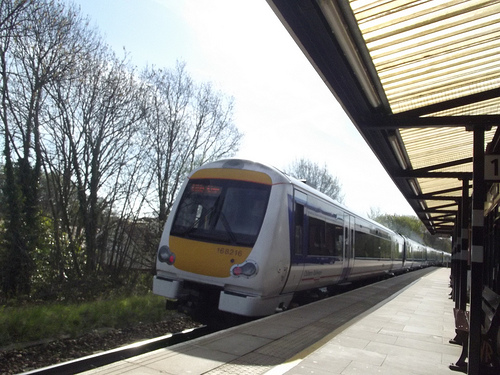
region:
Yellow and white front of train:
[147, 156, 287, 318]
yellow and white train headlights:
[227, 253, 267, 283]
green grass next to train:
[1, 285, 176, 338]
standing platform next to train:
[75, 262, 470, 374]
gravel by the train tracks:
[3, 307, 193, 374]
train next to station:
[143, 150, 468, 318]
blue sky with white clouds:
[1, 1, 425, 223]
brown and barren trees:
[0, 0, 244, 311]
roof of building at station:
[264, 0, 499, 239]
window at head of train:
[166, 175, 275, 247]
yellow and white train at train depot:
[164, 153, 426, 295]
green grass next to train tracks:
[10, 296, 152, 330]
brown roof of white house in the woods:
[101, 217, 151, 272]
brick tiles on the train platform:
[377, 315, 408, 374]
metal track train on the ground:
[65, 346, 152, 352]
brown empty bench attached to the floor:
[451, 269, 498, 373]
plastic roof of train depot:
[395, 70, 474, 199]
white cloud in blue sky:
[183, 12, 218, 45]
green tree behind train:
[380, 204, 423, 230]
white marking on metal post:
[471, 189, 487, 271]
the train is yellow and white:
[122, 145, 457, 321]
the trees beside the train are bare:
[2, 0, 367, 324]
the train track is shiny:
[8, 307, 238, 374]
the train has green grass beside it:
[1, 233, 198, 348]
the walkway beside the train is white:
[198, 260, 450, 374]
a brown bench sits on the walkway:
[431, 274, 498, 371]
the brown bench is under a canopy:
[256, 0, 499, 373]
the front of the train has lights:
[143, 141, 280, 328]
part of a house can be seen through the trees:
[69, 192, 178, 291]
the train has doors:
[280, 172, 362, 310]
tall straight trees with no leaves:
[20, 25, 160, 292]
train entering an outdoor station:
[116, 125, 321, 342]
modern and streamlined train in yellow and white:
[147, 140, 438, 325]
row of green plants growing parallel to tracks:
[0, 272, 201, 370]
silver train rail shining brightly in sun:
[33, 312, 208, 370]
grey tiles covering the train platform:
[197, 287, 435, 364]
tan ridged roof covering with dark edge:
[271, 17, 478, 163]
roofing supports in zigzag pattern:
[401, 163, 467, 238]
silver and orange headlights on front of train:
[150, 237, 266, 287]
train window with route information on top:
[166, 166, 229, 252]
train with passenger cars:
[278, 215, 448, 296]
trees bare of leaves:
[25, 82, 202, 294]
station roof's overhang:
[393, 69, 477, 244]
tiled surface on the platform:
[369, 273, 444, 370]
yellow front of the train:
[160, 158, 274, 294]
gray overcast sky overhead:
[242, 70, 316, 160]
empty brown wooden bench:
[451, 286, 494, 364]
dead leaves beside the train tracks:
[64, 325, 154, 363]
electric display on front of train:
[179, 179, 224, 199]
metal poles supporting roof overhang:
[448, 193, 487, 301]